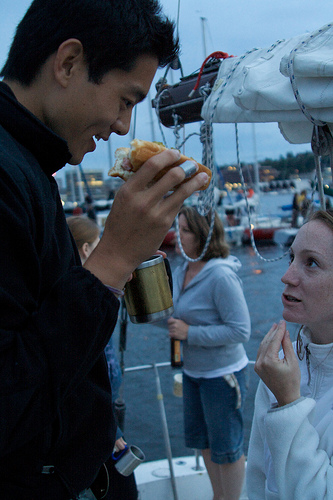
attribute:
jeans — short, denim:
[178, 365, 246, 466]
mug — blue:
[97, 435, 172, 488]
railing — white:
[124, 361, 191, 473]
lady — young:
[163, 202, 259, 450]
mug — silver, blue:
[110, 443, 145, 477]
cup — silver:
[117, 443, 147, 476]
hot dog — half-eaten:
[105, 135, 212, 198]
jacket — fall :
[0, 80, 123, 499]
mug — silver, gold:
[121, 253, 174, 323]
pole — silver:
[183, 15, 241, 176]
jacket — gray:
[164, 264, 252, 385]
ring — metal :
[157, 144, 210, 195]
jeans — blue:
[178, 360, 248, 460]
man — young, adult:
[1, 1, 212, 498]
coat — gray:
[165, 251, 253, 348]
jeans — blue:
[176, 352, 254, 469]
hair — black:
[1, 0, 181, 88]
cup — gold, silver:
[115, 253, 182, 323]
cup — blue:
[111, 443, 145, 477]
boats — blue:
[197, 192, 304, 247]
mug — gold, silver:
[117, 252, 179, 327]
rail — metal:
[122, 361, 185, 498]